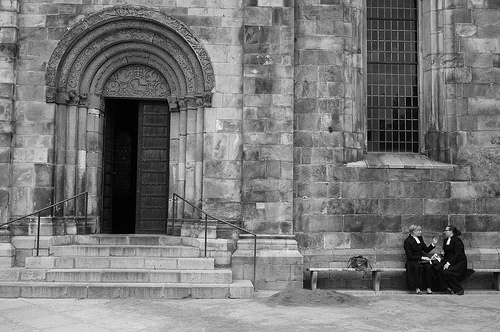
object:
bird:
[337, 234, 381, 281]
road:
[0, 298, 499, 332]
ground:
[385, 167, 422, 209]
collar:
[409, 234, 422, 239]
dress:
[403, 233, 435, 289]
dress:
[436, 235, 475, 294]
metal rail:
[172, 192, 257, 290]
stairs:
[0, 232, 253, 299]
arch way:
[43, 4, 217, 113]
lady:
[403, 224, 440, 294]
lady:
[434, 225, 476, 295]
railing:
[171, 192, 257, 290]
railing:
[0, 191, 89, 263]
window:
[362, 0, 425, 154]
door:
[135, 101, 170, 234]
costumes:
[403, 233, 475, 294]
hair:
[447, 225, 461, 236]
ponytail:
[455, 230, 461, 235]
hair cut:
[408, 224, 422, 234]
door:
[93, 64, 174, 235]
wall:
[205, 0, 367, 241]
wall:
[0, 0, 46, 215]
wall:
[449, 0, 500, 228]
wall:
[202, 159, 500, 232]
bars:
[365, 0, 418, 152]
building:
[0, 0, 500, 301]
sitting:
[433, 225, 475, 295]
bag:
[346, 255, 372, 272]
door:
[76, 50, 187, 235]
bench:
[306, 267, 500, 291]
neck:
[412, 234, 418, 238]